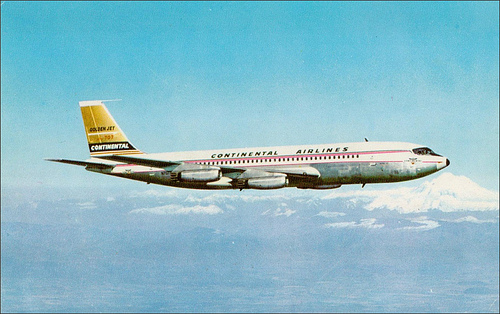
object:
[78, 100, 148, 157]
tail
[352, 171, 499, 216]
mountain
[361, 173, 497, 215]
snow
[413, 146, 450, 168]
cockpit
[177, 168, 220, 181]
engine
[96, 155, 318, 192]
wing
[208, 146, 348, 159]
logo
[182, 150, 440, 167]
cabin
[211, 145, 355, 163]
writing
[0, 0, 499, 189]
sky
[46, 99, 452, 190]
airplane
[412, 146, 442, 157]
windshield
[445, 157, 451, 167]
nose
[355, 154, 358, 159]
windows